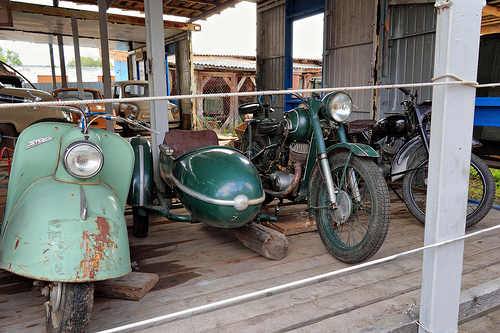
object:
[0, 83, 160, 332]
moped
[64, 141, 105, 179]
headlight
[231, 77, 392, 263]
moped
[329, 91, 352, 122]
headlight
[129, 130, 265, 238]
sidecar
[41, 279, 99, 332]
wheel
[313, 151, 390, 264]
wheel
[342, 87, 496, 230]
moped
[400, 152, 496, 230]
wheel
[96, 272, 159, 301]
piece of wood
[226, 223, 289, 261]
piece of wood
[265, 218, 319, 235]
piece of wood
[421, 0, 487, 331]
post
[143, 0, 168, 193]
post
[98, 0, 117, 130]
post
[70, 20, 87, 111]
post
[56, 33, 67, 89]
post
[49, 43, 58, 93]
post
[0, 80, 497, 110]
wire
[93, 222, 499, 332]
wire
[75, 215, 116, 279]
rust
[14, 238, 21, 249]
rust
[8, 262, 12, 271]
rust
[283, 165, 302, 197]
rust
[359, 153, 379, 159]
rust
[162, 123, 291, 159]
two seats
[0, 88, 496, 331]
cycle collection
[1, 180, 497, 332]
floor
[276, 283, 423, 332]
line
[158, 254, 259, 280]
line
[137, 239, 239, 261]
line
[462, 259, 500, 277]
line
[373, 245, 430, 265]
line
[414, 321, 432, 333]
rope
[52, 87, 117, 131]
car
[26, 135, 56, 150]
nameplate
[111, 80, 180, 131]
car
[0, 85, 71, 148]
car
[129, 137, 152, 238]
wheel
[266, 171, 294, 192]
gas tank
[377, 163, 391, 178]
gas tank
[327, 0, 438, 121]
building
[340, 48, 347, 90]
beam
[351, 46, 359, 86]
beam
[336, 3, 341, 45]
beam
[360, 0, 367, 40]
beam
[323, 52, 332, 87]
beam